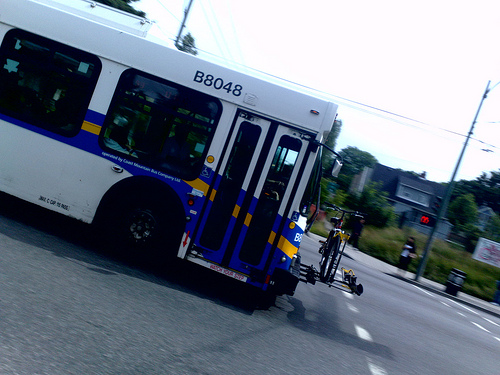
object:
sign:
[199, 163, 212, 178]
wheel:
[102, 183, 178, 265]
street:
[1, 218, 499, 372]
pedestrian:
[399, 237, 417, 271]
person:
[347, 219, 366, 249]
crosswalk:
[371, 242, 499, 373]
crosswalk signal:
[419, 211, 434, 226]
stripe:
[2, 106, 305, 284]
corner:
[347, 170, 429, 278]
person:
[160, 120, 194, 181]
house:
[348, 161, 453, 242]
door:
[187, 107, 318, 286]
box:
[444, 267, 469, 297]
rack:
[332, 227, 353, 286]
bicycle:
[316, 202, 366, 284]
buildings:
[329, 148, 455, 243]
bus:
[4, 0, 339, 298]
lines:
[354, 324, 375, 343]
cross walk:
[337, 265, 499, 374]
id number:
[192, 69, 242, 96]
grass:
[320, 207, 499, 302]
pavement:
[275, 205, 483, 360]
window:
[101, 69, 222, 182]